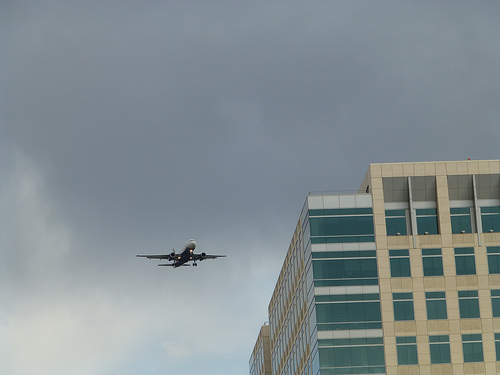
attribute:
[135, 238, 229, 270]
airplane — flying, low, landing, grey, big, large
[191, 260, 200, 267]
wheels — landing gear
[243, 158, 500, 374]
building — tall, flat, beige, facing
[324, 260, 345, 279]
window — dark, horizontal, green, blue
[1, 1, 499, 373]
sky — grey, cloudy, hazy